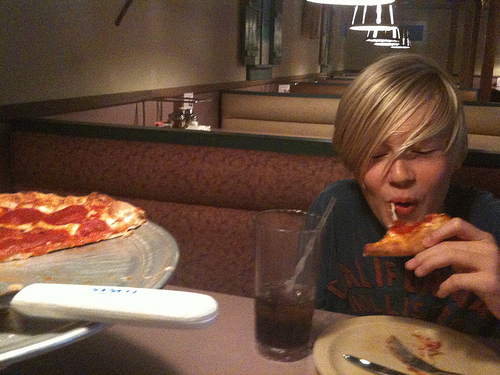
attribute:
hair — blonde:
[324, 51, 470, 175]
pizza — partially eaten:
[5, 184, 144, 261]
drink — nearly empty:
[250, 203, 324, 366]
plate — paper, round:
[318, 308, 488, 375]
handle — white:
[21, 276, 213, 331]